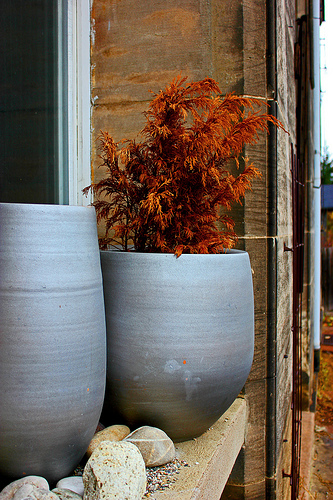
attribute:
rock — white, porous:
[80, 438, 150, 500]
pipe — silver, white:
[305, 0, 321, 352]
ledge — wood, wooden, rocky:
[149, 393, 247, 500]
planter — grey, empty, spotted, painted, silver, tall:
[101, 246, 256, 445]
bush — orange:
[86, 68, 293, 255]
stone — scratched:
[127, 425, 178, 470]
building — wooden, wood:
[1, 0, 310, 498]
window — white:
[0, 1, 90, 203]